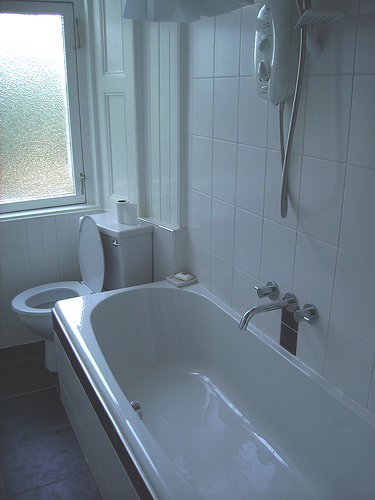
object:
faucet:
[237, 298, 290, 333]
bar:
[181, 272, 187, 276]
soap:
[175, 271, 194, 281]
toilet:
[9, 212, 154, 373]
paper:
[115, 198, 138, 226]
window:
[0, 0, 86, 212]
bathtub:
[52, 273, 375, 498]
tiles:
[0, 383, 97, 500]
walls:
[186, 0, 374, 411]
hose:
[278, 0, 309, 218]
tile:
[0, 383, 57, 457]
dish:
[166, 271, 198, 288]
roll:
[115, 199, 128, 224]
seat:
[10, 281, 90, 317]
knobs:
[252, 279, 320, 325]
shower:
[251, 2, 347, 107]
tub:
[253, 280, 280, 301]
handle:
[112, 239, 121, 247]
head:
[293, 5, 347, 57]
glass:
[24, 64, 96, 154]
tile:
[37, 419, 70, 435]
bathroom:
[0, 0, 375, 500]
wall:
[187, 4, 263, 314]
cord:
[277, 1, 307, 220]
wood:
[83, 0, 178, 230]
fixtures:
[238, 279, 318, 333]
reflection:
[189, 368, 290, 467]